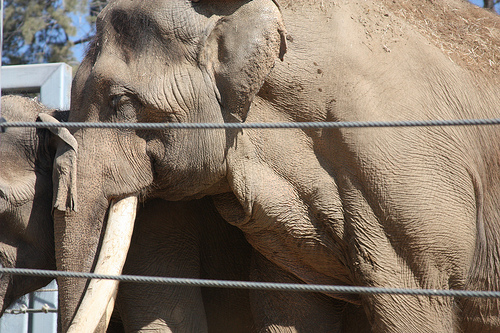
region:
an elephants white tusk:
[67, 195, 140, 332]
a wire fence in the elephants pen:
[1, 119, 498, 127]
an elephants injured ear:
[206, 0, 286, 152]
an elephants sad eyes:
[105, 85, 127, 105]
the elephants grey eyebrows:
[105, 83, 126, 99]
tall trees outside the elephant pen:
[2, 0, 84, 62]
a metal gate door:
[1, 63, 71, 107]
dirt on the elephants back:
[380, 2, 499, 77]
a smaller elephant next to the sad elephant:
[1, 94, 78, 312]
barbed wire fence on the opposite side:
[6, 301, 57, 316]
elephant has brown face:
[49, 19, 261, 307]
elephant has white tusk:
[60, 178, 174, 298]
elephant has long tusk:
[70, 207, 142, 326]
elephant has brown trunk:
[39, 64, 93, 327]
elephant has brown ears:
[215, 15, 297, 180]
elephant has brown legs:
[322, 205, 464, 330]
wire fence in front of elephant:
[48, 131, 478, 315]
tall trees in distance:
[20, 2, 75, 51]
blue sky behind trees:
[10, 6, 107, 75]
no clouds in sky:
[37, 3, 104, 71]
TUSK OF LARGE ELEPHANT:
[56, 195, 146, 332]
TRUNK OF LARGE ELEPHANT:
[51, 198, 103, 331]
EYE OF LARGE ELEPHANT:
[98, 81, 144, 105]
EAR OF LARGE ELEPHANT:
[191, 4, 273, 210]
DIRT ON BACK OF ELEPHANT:
[413, 8, 477, 71]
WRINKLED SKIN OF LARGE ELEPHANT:
[348, 218, 396, 279]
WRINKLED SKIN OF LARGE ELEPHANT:
[148, 78, 195, 111]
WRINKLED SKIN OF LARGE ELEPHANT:
[155, 11, 204, 41]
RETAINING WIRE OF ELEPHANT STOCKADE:
[181, 114, 279, 155]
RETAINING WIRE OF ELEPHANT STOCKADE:
[103, 268, 188, 313]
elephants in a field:
[53, 60, 419, 329]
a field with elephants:
[12, 48, 497, 293]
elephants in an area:
[32, 37, 464, 325]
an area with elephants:
[18, 17, 430, 322]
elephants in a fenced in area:
[47, 36, 497, 322]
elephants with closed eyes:
[19, 17, 482, 269]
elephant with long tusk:
[15, 35, 311, 331]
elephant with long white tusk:
[80, 160, 219, 330]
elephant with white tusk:
[49, 153, 233, 332]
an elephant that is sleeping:
[11, 12, 403, 331]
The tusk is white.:
[62, 191, 136, 330]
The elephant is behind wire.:
[10, 79, 497, 325]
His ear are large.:
[195, 0, 292, 175]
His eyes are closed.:
[104, 86, 139, 117]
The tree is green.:
[0, 0, 88, 60]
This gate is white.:
[3, 64, 70, 325]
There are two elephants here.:
[4, 1, 497, 326]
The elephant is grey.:
[49, 4, 486, 317]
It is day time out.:
[3, 0, 109, 65]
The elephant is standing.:
[58, 3, 498, 315]